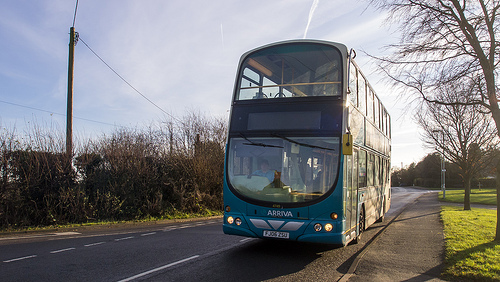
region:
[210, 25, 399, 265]
blue double decker bus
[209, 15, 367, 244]
two windows on the front of bus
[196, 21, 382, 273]
empty bus on road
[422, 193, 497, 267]
green grass next to concrete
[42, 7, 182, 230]
telephone pole and wires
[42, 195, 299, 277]
black concrete one lane road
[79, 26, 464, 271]
bus on side of the road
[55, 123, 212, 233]
bushes with no leaves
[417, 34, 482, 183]
tree with no leaves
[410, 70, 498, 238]
tree by the side of the road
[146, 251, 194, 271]
solid white line in street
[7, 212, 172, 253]
cluster of broken white lines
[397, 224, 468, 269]
shadow cast on the ground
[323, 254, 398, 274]
grey edge of side walk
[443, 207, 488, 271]
large patch of green grass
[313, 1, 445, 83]
white streaks in the sky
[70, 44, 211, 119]
long electrical pole in the air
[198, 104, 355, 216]
wide mirror in the blue bus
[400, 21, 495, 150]
selections of bare trees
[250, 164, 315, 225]
man driving blue bus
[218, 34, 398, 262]
the bus is green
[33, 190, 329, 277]
the lines on road are white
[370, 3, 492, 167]
the trees have no leaves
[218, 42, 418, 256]
the bus has 2 levels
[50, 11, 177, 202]
an electric pole is on the right side of bus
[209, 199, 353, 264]
the lights on bus are on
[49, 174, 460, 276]
the road is black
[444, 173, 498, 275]
the grass is green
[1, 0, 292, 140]
the sky is blue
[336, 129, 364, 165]
the side mirror is yellow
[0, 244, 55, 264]
Broken white line on street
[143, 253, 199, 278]
Solid white on street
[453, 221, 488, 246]
Small patch of green grass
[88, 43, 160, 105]
Power line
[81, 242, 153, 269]
Small section of the black street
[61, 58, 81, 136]
Pole that connects to power line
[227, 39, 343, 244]
Front of the teal bus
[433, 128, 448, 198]
Gray street light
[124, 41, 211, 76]
Clear white cloud in the sky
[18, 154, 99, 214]
Bushes with no leaves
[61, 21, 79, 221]
electrical pole on the side of the road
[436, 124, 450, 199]
lamp post on the corner of the street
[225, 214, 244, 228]
headlights on the bus driving down the road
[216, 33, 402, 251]
double decker bus driving down the road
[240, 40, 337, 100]
Window on the top level of the bus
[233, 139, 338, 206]
Drivers window on the main level of the bus.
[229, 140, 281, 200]
driver in the drivers seat.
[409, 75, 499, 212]
bare tree on the corner of the street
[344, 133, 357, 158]
side mirror on this bus is yellow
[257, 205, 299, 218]
arriva is the name of the bus company